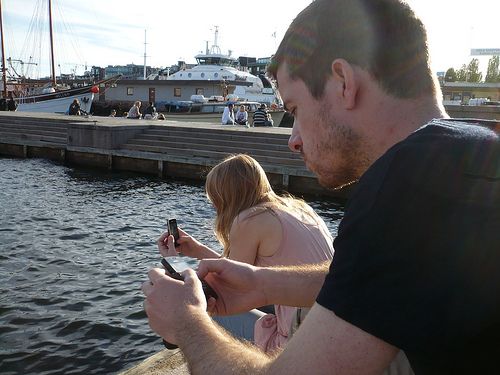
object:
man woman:
[141, 0, 497, 374]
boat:
[0, 0, 122, 118]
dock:
[116, 346, 189, 371]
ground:
[356, 94, 407, 152]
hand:
[141, 267, 210, 345]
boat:
[94, 33, 289, 126]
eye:
[289, 104, 297, 118]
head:
[206, 155, 272, 218]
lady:
[158, 154, 335, 373]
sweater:
[316, 119, 497, 373]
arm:
[202, 210, 443, 374]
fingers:
[146, 267, 184, 285]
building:
[92, 79, 253, 107]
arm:
[255, 265, 333, 309]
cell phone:
[167, 217, 179, 247]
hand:
[165, 227, 195, 253]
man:
[67, 96, 82, 116]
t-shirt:
[310, 116, 498, 373]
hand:
[157, 230, 179, 255]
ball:
[91, 83, 102, 93]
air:
[6, 3, 498, 364]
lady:
[221, 102, 239, 125]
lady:
[126, 99, 143, 119]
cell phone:
[160, 255, 222, 305]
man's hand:
[191, 255, 260, 319]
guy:
[140, 0, 500, 374]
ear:
[331, 57, 362, 112]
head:
[266, 0, 442, 188]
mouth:
[302, 154, 314, 172]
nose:
[289, 125, 309, 155]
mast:
[0, 2, 8, 95]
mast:
[47, 2, 57, 88]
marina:
[4, 3, 493, 183]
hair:
[204, 152, 303, 259]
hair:
[266, 0, 433, 97]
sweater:
[253, 107, 268, 123]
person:
[249, 101, 272, 127]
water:
[0, 146, 345, 374]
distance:
[2, 0, 483, 126]